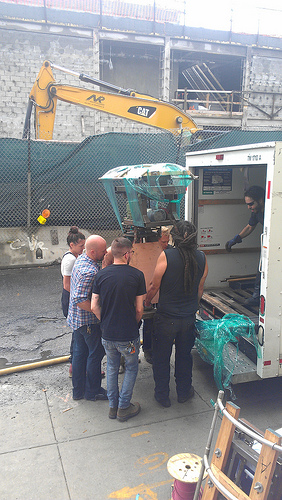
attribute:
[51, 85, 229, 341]
equipment — heavy, large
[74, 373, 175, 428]
boot — brown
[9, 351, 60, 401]
hose — yellow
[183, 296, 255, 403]
plastic — green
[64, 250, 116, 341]
shirt — blue, plaid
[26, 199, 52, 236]
caterpillar — yellow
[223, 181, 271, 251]
man — wearing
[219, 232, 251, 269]
glove — blue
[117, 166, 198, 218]
dreadlock — long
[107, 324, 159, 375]
keys — dangling, hanging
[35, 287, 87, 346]
woman — wearing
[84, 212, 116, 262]
man — bald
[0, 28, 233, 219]
machine — heavy, yellow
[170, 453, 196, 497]
wire — pink, red, spool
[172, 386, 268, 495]
pallet — wooden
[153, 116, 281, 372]
truck — white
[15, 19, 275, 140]
building — gray, opening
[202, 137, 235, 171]
light — orange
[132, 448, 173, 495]
writing — yellow, white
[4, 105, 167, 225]
fence — metal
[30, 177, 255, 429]
people — group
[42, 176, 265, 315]
men — carrying, holding